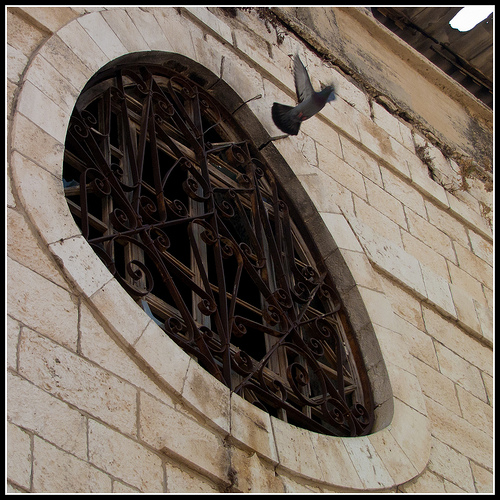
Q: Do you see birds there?
A: Yes, there is a bird.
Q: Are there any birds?
A: Yes, there is a bird.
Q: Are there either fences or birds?
A: Yes, there is a bird.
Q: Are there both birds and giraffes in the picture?
A: No, there is a bird but no giraffes.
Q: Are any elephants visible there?
A: No, there are no elephants.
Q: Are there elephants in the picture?
A: No, there are no elephants.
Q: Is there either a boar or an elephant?
A: No, there are no elephants or boars.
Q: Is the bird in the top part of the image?
A: Yes, the bird is in the top of the image.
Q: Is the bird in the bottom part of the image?
A: No, the bird is in the top of the image.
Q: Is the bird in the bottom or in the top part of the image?
A: The bird is in the top of the image.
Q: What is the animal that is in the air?
A: The animal is a bird.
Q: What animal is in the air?
A: The animal is a bird.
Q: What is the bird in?
A: The bird is in the air.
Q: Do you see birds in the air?
A: Yes, there is a bird in the air.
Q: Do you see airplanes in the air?
A: No, there is a bird in the air.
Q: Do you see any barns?
A: No, there are no barns.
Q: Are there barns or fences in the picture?
A: No, there are no barns or fences.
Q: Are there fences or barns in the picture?
A: No, there are no barns or fences.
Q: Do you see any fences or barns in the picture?
A: No, there are no barns or fences.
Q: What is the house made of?
A: The house is made of brick.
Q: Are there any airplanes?
A: No, there are no airplanes.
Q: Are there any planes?
A: No, there are no planes.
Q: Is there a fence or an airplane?
A: No, there are no airplanes or fences.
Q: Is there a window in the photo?
A: Yes, there is a window.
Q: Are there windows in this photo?
A: Yes, there is a window.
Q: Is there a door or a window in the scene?
A: Yes, there is a window.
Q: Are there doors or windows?
A: Yes, there is a window.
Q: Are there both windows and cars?
A: No, there is a window but no cars.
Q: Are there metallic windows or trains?
A: Yes, there is a metal window.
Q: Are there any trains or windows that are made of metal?
A: Yes, the window is made of metal.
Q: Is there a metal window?
A: Yes, there is a window that is made of metal.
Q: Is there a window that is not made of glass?
A: Yes, there is a window that is made of metal.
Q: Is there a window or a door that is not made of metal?
A: No, there is a window but it is made of metal.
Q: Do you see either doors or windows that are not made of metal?
A: No, there is a window but it is made of metal.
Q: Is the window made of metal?
A: Yes, the window is made of metal.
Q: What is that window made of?
A: The window is made of metal.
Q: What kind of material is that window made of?
A: The window is made of metal.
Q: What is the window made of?
A: The window is made of metal.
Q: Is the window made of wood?
A: No, the window is made of metal.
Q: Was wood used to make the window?
A: No, the window is made of metal.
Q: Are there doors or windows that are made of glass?
A: No, there is a window but it is made of metal.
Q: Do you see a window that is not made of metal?
A: No, there is a window but it is made of metal.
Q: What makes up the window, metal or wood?
A: The window is made of metal.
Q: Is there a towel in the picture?
A: No, there are no towels.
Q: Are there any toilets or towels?
A: No, there are no towels or toilets.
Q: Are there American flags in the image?
A: No, there are no American flags.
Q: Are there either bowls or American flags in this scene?
A: No, there are no American flags or bowls.